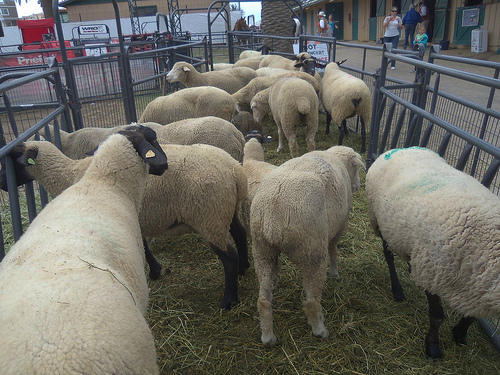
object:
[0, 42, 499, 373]
ground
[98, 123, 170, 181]
head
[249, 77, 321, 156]
sheep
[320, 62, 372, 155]
sheep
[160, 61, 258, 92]
sheep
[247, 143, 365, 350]
sheep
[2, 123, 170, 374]
sheep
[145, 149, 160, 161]
identification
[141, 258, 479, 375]
hay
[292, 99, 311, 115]
tail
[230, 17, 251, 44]
horse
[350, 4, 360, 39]
stall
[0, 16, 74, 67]
booth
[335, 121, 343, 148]
legs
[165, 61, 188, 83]
face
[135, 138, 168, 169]
ear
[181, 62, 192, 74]
ear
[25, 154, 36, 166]
tag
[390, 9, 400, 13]
sunglasses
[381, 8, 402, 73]
woman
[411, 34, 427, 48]
shirt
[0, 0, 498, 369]
pen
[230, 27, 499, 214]
railing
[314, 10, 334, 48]
person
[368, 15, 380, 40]
door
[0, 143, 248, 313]
sheep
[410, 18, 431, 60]
child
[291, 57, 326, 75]
sheep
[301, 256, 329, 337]
leg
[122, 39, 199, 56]
bar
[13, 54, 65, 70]
sign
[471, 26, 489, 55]
stand